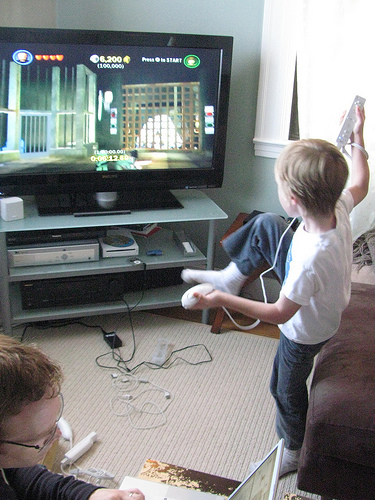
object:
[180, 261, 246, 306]
socks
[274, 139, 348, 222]
hair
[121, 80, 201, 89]
bars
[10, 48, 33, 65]
character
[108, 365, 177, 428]
headphones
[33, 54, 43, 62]
hearts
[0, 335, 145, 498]
boy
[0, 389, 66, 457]
glasses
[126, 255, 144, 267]
ipod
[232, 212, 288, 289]
leg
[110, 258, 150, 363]
cord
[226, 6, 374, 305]
walls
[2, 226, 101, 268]
equipment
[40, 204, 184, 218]
bar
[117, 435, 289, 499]
laptop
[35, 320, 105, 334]
cord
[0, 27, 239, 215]
tv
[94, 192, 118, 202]
speaker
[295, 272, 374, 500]
sofa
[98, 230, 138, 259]
video game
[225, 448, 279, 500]
screen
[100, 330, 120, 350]
power supply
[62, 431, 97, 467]
controller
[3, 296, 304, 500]
floor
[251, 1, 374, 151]
casement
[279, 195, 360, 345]
t-shirt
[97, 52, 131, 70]
score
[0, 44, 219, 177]
screen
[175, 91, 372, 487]
boy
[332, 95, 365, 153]
control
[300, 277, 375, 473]
cushion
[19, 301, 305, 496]
carpet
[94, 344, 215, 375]
cords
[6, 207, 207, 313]
entertainment center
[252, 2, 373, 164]
window